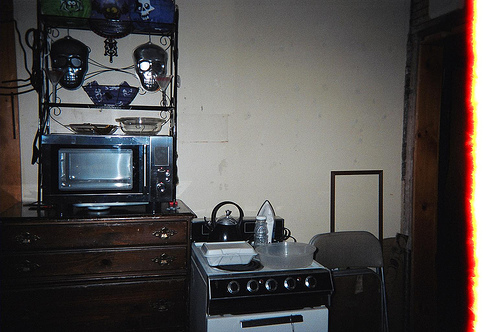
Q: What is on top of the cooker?
A: A bowl.